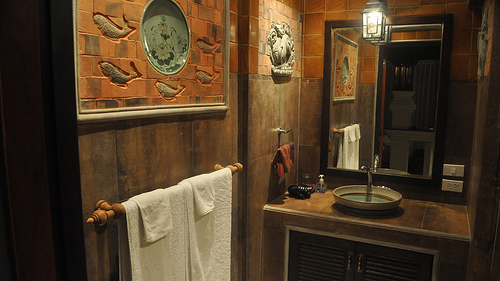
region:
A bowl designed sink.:
[330, 162, 404, 215]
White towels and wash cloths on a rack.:
[81, 160, 242, 278]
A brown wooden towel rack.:
[85, 150, 241, 225]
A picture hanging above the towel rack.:
[65, 0, 230, 123]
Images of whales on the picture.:
[90, 8, 216, 98]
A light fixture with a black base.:
[357, 0, 387, 41]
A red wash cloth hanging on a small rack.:
[272, 125, 297, 177]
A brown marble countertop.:
[265, 181, 472, 241]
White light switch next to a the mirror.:
[441, 162, 466, 177]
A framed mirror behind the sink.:
[321, 21, 466, 185]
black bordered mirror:
[317, 12, 452, 188]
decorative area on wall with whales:
[74, 0, 231, 124]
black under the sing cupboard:
[286, 230, 436, 280]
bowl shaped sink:
[332, 170, 402, 210]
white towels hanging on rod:
[84, 161, 242, 279]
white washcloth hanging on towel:
[130, 187, 174, 241]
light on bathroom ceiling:
[362, 0, 387, 39]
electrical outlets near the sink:
[441, 179, 462, 191]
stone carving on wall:
[266, 19, 294, 79]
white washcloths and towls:
[121, 167, 231, 279]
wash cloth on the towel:
[129, 183, 184, 247]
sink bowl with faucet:
[332, 156, 402, 213]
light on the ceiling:
[353, 3, 394, 47]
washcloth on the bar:
[270, 143, 296, 184]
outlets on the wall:
[437, 180, 464, 195]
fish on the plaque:
[88, 12, 136, 39]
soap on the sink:
[311, 170, 326, 195]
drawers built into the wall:
[271, 218, 445, 278]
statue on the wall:
[265, 16, 297, 83]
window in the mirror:
[383, 54, 430, 131]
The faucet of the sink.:
[360, 158, 374, 183]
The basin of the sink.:
[332, 178, 401, 213]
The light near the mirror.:
[361, 5, 386, 45]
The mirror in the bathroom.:
[321, 25, 444, 185]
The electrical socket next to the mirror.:
[443, 178, 465, 193]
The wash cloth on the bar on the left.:
[139, 193, 176, 245]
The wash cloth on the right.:
[194, 178, 216, 211]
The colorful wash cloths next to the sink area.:
[281, 144, 296, 169]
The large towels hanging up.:
[113, 187, 240, 279]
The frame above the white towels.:
[69, 3, 229, 113]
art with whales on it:
[65, 0, 236, 133]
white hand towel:
[130, 185, 177, 250]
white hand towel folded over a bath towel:
[118, 183, 190, 279]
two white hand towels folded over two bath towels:
[121, 163, 235, 278]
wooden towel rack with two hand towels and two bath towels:
[84, 156, 247, 278]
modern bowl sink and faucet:
[328, 161, 408, 221]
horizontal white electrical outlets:
[437, 176, 468, 196]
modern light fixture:
[352, 1, 399, 50]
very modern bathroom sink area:
[245, 0, 497, 280]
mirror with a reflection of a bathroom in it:
[315, 12, 454, 184]